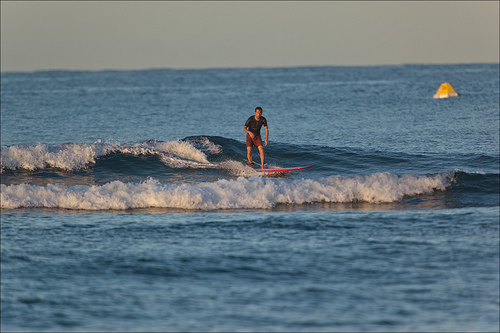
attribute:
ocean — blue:
[148, 124, 320, 284]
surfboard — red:
[209, 141, 339, 197]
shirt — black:
[248, 114, 267, 141]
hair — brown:
[249, 102, 266, 117]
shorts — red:
[235, 131, 267, 171]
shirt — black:
[246, 116, 270, 148]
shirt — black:
[241, 116, 273, 146]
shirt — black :
[246, 116, 268, 137]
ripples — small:
[12, 179, 107, 212]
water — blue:
[7, 68, 497, 331]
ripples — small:
[5, 269, 156, 327]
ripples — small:
[63, 265, 144, 320]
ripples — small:
[88, 275, 170, 322]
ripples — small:
[124, 285, 227, 318]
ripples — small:
[175, 289, 306, 319]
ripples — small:
[242, 285, 322, 326]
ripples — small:
[254, 278, 324, 325]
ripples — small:
[307, 285, 407, 325]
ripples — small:
[354, 278, 434, 320]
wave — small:
[0, 126, 493, 218]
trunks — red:
[244, 130, 261, 150]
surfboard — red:
[233, 158, 313, 178]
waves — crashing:
[0, 132, 491, 225]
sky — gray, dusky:
[4, 5, 495, 72]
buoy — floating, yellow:
[429, 75, 457, 111]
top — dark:
[241, 115, 271, 138]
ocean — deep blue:
[4, 65, 498, 331]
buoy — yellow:
[431, 66, 471, 106]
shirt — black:
[243, 116, 266, 138]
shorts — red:
[238, 130, 273, 151]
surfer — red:
[243, 105, 268, 169]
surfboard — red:
[258, 163, 316, 174]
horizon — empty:
[0, 62, 430, 102]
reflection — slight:
[160, 174, 362, 211]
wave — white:
[0, 166, 457, 209]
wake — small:
[173, 155, 242, 175]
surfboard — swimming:
[258, 162, 314, 175]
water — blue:
[24, 220, 473, 330]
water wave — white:
[0, 172, 458, 209]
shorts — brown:
[245, 134, 261, 147]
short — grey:
[254, 135, 264, 152]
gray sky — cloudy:
[17, 1, 484, 63]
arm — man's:
[263, 121, 271, 147]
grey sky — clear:
[19, 0, 482, 61]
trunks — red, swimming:
[244, 133, 264, 147]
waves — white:
[3, 136, 223, 166]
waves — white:
[1, 171, 446, 216]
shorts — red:
[245, 136, 261, 150]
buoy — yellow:
[428, 82, 458, 100]